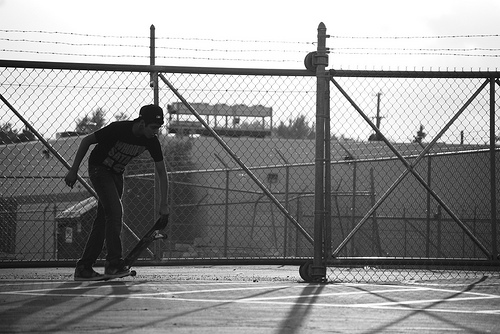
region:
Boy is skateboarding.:
[55, 102, 180, 284]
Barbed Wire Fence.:
[0, 23, 498, 285]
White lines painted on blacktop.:
[4, 281, 497, 312]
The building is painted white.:
[3, 143, 498, 270]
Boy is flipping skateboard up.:
[60, 103, 182, 287]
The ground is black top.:
[3, 260, 498, 330]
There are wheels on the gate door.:
[299, 47, 336, 286]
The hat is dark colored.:
[130, 101, 164, 126]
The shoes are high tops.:
[74, 257, 131, 278]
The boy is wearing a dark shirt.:
[63, 98, 169, 288]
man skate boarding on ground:
[21, 88, 219, 293]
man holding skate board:
[26, 92, 182, 297]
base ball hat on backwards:
[128, 90, 188, 128]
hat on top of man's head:
[117, 97, 174, 137]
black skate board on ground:
[121, 220, 168, 274]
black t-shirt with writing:
[68, 119, 166, 182]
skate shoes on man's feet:
[64, 263, 134, 285]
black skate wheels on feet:
[137, 233, 174, 244]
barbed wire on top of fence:
[0, 31, 472, 66]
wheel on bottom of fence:
[291, 262, 317, 279]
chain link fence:
[1, 60, 496, 263]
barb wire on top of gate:
[1, 28, 498, 70]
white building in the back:
[4, 102, 496, 257]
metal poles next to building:
[215, 143, 478, 254]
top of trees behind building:
[2, 110, 352, 139]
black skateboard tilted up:
[124, 217, 168, 276]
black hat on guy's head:
[135, 105, 166, 122]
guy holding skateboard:
[52, 103, 172, 280]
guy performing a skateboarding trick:
[67, 105, 168, 280]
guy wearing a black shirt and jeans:
[67, 108, 169, 278]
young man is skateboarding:
[63, 102, 172, 279]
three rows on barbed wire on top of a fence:
[0, 24, 495, 65]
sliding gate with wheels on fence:
[297, 20, 496, 280]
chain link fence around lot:
[0, 58, 497, 283]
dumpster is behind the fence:
[54, 192, 96, 262]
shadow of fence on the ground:
[2, 281, 497, 326]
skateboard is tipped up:
[111, 209, 169, 279]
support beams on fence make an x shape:
[329, 75, 499, 257]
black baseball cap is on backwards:
[132, 103, 164, 127]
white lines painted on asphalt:
[3, 285, 498, 316]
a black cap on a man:
[135, 104, 165, 122]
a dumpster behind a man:
[53, 187, 102, 270]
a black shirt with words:
[89, 119, 169, 178]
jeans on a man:
[77, 168, 131, 265]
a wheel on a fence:
[295, 255, 340, 285]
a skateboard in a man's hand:
[118, 210, 171, 279]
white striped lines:
[0, 269, 497, 315]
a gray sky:
[0, 13, 498, 131]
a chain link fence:
[1, 70, 497, 269]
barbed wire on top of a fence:
[0, 25, 319, 59]